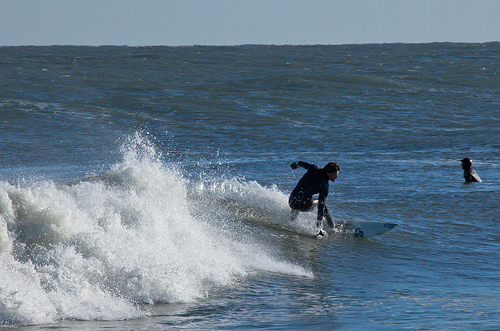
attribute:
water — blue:
[2, 43, 497, 330]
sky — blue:
[0, 4, 497, 49]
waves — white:
[1, 130, 317, 328]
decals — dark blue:
[344, 217, 403, 243]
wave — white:
[0, 162, 313, 329]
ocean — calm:
[5, 42, 498, 154]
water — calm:
[327, 48, 497, 328]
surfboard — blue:
[333, 211, 400, 243]